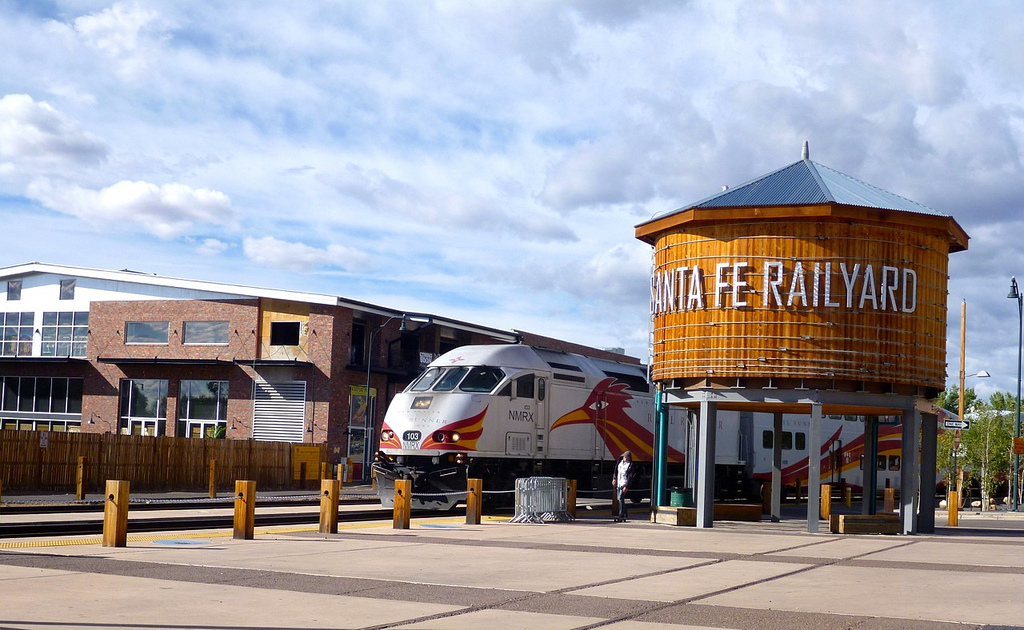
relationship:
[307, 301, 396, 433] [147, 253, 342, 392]
wall on building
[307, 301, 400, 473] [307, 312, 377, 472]
wall on building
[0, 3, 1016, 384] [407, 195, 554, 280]
clouds in sky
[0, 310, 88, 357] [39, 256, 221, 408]
window on building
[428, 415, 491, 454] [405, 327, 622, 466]
headlight on train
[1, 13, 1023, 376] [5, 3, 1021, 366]
clouds in sky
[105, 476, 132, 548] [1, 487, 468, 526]
post near track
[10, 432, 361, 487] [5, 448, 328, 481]
fence near railings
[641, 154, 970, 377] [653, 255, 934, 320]
tank with letterings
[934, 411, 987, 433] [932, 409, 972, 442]
sign with arrow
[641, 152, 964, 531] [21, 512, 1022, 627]
tower sitting on a platform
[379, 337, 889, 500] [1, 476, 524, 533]
train sitting on track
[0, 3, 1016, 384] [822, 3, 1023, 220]
clouds in back corner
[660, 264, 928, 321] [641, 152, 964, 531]
name on tower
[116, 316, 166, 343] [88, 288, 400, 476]
window on building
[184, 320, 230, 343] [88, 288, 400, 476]
window on building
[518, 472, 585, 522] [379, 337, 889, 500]
box next to train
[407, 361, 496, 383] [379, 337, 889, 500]
window on a train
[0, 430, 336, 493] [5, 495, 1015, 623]
fence next to platform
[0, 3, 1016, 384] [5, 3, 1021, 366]
clouds in sky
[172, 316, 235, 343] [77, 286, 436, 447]
window on building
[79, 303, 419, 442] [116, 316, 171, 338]
window on building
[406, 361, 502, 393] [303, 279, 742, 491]
window on train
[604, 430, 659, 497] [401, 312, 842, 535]
man by train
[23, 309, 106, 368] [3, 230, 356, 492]
window on building